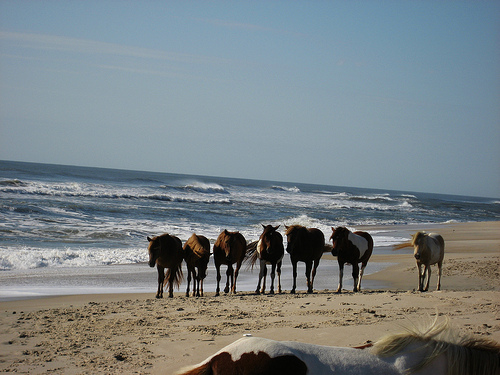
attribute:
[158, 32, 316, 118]
sky — blue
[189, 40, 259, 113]
clouds — white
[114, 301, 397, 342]
beach — sandy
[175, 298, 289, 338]
sand — brown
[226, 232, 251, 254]
fur — brown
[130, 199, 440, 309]
animal — walking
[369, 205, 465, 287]
horse — walking, brown, grey, beige, blonde, swinging, white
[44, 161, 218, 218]
waves — water, foam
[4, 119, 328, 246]
ocean — distance